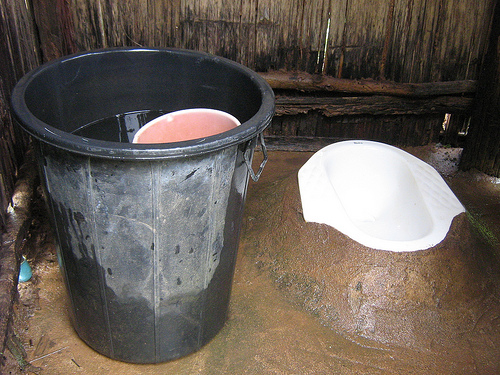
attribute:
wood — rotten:
[254, 0, 476, 152]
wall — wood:
[0, 0, 494, 160]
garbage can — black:
[8, 42, 279, 368]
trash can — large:
[12, 42, 274, 354]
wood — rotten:
[19, 0, 489, 140]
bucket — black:
[26, 36, 280, 369]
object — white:
[130, 105, 231, 149]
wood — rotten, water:
[252, 12, 468, 151]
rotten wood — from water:
[271, 50, 405, 123]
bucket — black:
[57, 59, 304, 340]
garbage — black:
[18, 35, 283, 362]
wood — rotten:
[273, 27, 471, 99]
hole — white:
[289, 134, 464, 251]